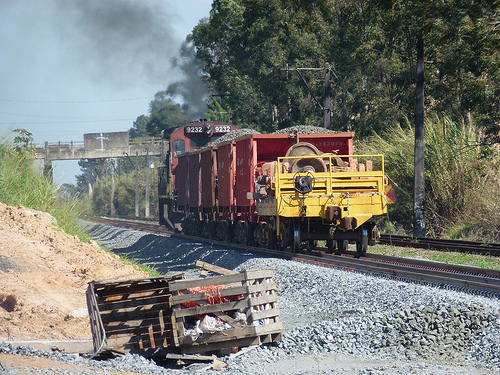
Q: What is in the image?
A: Small train.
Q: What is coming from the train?
A: Smoke.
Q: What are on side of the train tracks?
A: Rocks.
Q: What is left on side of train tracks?
A: Wooden boxes.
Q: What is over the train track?
A: Overpass.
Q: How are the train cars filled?
A: Gravel.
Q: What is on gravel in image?
A: Shadow of train.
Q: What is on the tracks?
A: A train.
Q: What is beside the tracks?
A: Gravel.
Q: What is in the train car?
A: Crushed rock.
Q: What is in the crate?
A: Debris.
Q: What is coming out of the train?
A: Smoke.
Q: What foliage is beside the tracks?
A: Large trees and thick vegetation.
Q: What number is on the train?
A: Number 9232.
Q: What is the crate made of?
A: Wood.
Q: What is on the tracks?
A: A train.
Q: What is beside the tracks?
A: A crate.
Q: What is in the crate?
A: Debris.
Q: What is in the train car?
A: Crushed rock.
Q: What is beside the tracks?
A: Gravel.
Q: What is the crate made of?
A: Wood.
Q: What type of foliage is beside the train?
A: Large trees and thick vegetation.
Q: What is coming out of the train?
A: Black smoke.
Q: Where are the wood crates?
A: Near the tracks.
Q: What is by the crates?
A: A pile of dirt.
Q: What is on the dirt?
A: Green grass.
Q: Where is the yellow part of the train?
A: On the back.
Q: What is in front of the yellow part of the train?
A: The red part of the train.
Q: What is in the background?
A: A gray bridge.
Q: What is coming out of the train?
A: Black smoke.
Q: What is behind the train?
A: Trees.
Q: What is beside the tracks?
A: Gray rocks.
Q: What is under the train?
A: Brown tracks.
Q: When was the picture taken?
A: Daytime.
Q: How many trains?
A: One.